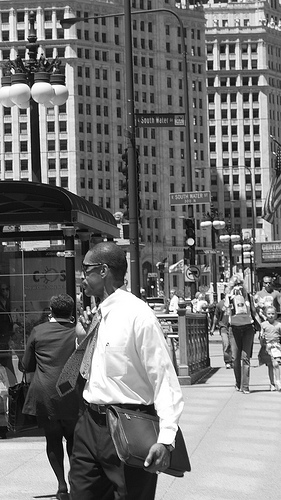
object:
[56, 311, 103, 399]
tie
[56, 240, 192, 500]
man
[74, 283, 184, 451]
shirt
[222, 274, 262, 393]
woman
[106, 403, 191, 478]
portfolio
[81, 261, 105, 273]
glasses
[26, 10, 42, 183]
pole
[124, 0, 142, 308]
pole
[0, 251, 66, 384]
window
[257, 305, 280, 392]
people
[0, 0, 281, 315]
buildings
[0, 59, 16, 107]
lights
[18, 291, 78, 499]
person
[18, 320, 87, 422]
coat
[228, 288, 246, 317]
bag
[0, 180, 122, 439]
bus stop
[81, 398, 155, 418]
belt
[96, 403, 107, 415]
buckle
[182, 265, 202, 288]
sign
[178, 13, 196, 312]
pole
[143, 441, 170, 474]
hand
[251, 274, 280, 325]
man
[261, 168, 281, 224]
flag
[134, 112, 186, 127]
sign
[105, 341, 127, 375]
pocket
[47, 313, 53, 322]
earrings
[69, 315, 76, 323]
earrings